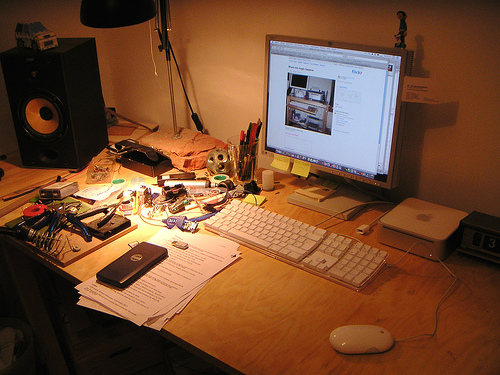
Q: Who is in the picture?
A: No one.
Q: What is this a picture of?
A: An office space.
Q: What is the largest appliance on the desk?
A: A computer.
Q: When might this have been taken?
A: At night.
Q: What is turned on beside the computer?
A: A lamp.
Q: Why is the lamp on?
A: It's dark in the room.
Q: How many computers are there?
A: One.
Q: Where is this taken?
A: In a house.